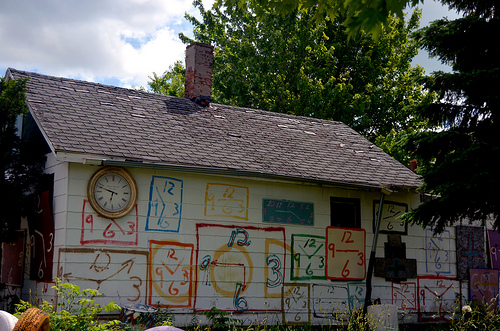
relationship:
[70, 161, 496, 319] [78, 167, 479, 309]
wall has art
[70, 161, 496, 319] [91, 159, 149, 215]
wall has clock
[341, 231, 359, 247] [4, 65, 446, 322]
number on side of house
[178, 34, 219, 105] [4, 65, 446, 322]
chimny on top of house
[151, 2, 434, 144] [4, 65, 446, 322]
tree beside house